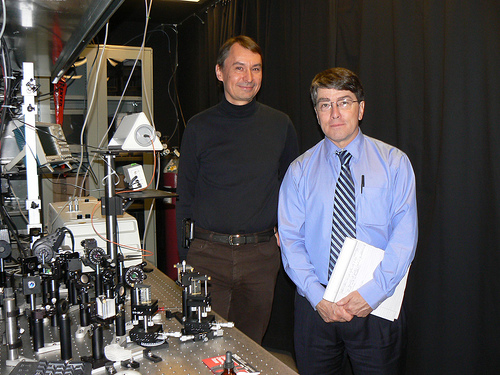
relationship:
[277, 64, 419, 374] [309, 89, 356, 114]
man wearing glasses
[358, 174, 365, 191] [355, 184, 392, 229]
pen in pocket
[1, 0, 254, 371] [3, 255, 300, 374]
equipment on workbench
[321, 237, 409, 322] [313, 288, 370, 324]
papers in hands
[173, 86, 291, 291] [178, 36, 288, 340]
shirt on man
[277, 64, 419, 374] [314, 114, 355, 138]
man has a mouth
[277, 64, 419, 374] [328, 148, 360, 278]
man wearing striped tie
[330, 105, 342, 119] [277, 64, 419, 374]
nose of an man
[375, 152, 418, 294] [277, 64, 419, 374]
arm of an man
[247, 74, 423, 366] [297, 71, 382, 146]
glasses on face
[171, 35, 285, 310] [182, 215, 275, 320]
man wearing pants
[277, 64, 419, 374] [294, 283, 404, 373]
man wearing pants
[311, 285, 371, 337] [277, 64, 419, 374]
hands of man